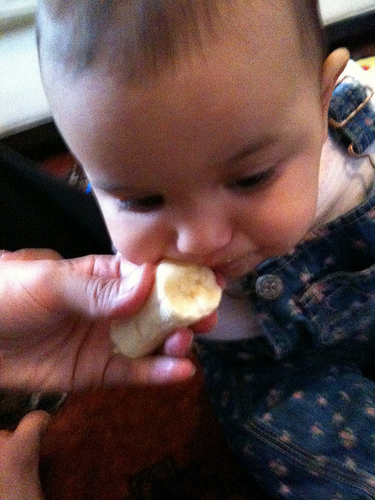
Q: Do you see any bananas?
A: Yes, there is a banana.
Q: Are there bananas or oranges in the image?
A: Yes, there is a banana.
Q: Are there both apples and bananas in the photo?
A: No, there is a banana but no apples.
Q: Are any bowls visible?
A: No, there are no bowls.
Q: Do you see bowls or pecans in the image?
A: No, there are no bowls or pecans.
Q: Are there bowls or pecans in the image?
A: No, there are no bowls or pecans.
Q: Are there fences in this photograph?
A: No, there are no fences.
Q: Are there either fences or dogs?
A: No, there are no fences or dogs.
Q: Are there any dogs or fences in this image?
A: No, there are no fences or dogs.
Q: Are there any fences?
A: No, there are no fences.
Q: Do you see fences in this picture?
A: No, there are no fences.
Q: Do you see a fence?
A: No, there are no fences.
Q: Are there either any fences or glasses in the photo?
A: No, there are no fences or glasses.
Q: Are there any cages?
A: No, there are no cages.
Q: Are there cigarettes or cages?
A: No, there are no cages or cigarettes.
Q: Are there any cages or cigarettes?
A: No, there are no cages or cigarettes.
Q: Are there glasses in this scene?
A: No, there are no glasses.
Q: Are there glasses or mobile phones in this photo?
A: No, there are no glasses or mobile phones.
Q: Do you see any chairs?
A: No, there are no chairs.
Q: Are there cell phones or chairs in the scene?
A: No, there are no chairs or cell phones.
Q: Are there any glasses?
A: No, there are no glasses.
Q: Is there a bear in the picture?
A: No, there are no bears.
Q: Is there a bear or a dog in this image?
A: No, there are no bears or dogs.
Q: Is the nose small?
A: Yes, the nose is small.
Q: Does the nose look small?
A: Yes, the nose is small.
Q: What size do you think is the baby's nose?
A: The nose is small.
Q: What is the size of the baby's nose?
A: The nose is small.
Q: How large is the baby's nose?
A: The nose is small.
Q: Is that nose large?
A: No, the nose is small.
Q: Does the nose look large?
A: No, the nose is small.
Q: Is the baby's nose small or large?
A: The nose is small.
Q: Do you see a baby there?
A: Yes, there is a baby.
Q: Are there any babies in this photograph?
A: Yes, there is a baby.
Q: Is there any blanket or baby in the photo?
A: Yes, there is a baby.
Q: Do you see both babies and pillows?
A: No, there is a baby but no pillows.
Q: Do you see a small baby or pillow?
A: Yes, there is a small baby.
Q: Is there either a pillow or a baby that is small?
A: Yes, the baby is small.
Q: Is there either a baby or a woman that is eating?
A: Yes, the baby is eating.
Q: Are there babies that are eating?
A: Yes, there is a baby that is eating.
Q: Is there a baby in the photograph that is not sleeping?
A: Yes, there is a baby that is eating.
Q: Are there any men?
A: No, there are no men.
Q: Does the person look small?
A: Yes, the baby is small.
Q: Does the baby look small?
A: Yes, the baby is small.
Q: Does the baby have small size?
A: Yes, the baby is small.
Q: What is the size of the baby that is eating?
A: The baby is small.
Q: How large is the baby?
A: The baby is small.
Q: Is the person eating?
A: Yes, the baby is eating.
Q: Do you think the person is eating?
A: Yes, the baby is eating.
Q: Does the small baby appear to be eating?
A: Yes, the baby is eating.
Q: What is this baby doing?
A: The baby is eating.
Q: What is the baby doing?
A: The baby is eating.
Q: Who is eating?
A: The baby is eating.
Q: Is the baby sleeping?
A: No, the baby is eating.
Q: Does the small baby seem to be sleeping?
A: No, the baby is eating.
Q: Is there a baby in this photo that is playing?
A: No, there is a baby but he is eating.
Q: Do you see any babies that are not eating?
A: No, there is a baby but he is eating.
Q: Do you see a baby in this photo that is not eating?
A: No, there is a baby but he is eating.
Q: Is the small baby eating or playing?
A: The baby is eating.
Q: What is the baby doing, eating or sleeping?
A: The baby is eating.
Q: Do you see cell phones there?
A: No, there are no cell phones.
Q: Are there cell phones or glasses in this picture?
A: No, there are no cell phones or glasses.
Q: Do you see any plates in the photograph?
A: No, there are no plates.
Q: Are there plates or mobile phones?
A: No, there are no plates or mobile phones.